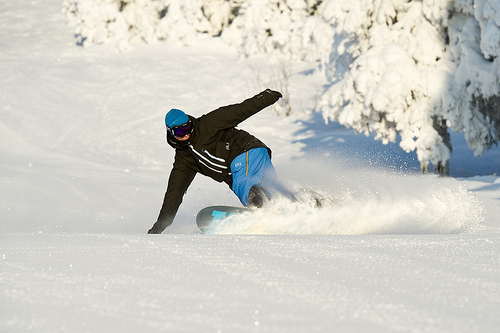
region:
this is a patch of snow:
[58, 107, 88, 132]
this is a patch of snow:
[278, 277, 311, 302]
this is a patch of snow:
[23, 267, 45, 303]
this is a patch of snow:
[86, 272, 146, 320]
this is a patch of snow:
[212, 275, 289, 310]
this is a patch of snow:
[75, 58, 96, 143]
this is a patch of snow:
[318, 165, 349, 256]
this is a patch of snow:
[288, 190, 399, 260]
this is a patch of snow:
[70, 61, 156, 117]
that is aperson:
[161, 97, 280, 214]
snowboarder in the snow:
[122, 75, 347, 252]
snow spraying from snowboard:
[300, 187, 460, 244]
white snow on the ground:
[41, 245, 262, 311]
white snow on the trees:
[358, 29, 443, 126]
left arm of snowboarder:
[223, 86, 289, 123]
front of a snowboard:
[196, 197, 251, 239]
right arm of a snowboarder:
[148, 162, 193, 244]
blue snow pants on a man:
[220, 143, 295, 205]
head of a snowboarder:
[150, 103, 199, 148]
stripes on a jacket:
[188, 142, 235, 182]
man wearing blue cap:
[171, 112, 183, 119]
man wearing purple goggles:
[173, 121, 195, 137]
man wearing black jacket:
[206, 120, 220, 128]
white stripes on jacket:
[191, 148, 214, 165]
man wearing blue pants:
[253, 156, 263, 168]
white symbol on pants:
[233, 160, 243, 175]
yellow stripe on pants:
[242, 150, 252, 175]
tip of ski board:
[194, 206, 209, 232]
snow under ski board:
[238, 209, 303, 231]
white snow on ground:
[168, 281, 281, 308]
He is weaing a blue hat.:
[149, 105, 193, 130]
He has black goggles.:
[168, 116, 193, 134]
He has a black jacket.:
[149, 105, 285, 191]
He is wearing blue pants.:
[222, 151, 296, 202]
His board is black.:
[175, 190, 350, 237]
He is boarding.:
[128, 90, 340, 256]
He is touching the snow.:
[118, 170, 188, 272]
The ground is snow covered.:
[24, 12, 450, 328]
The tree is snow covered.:
[79, 0, 493, 163]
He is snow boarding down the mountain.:
[129, 76, 434, 324]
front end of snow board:
[192, 203, 252, 234]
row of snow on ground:
[2, 229, 497, 330]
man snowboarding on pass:
[143, 85, 338, 242]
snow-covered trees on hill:
[60, 0, 499, 177]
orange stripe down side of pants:
[244, 147, 250, 174]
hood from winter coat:
[162, 107, 195, 148]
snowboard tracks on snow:
[52, 53, 153, 183]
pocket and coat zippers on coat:
[187, 142, 231, 176]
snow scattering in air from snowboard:
[214, 180, 489, 241]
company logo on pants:
[231, 157, 243, 168]